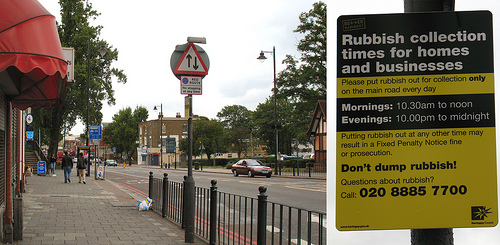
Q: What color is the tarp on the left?
A: Red.